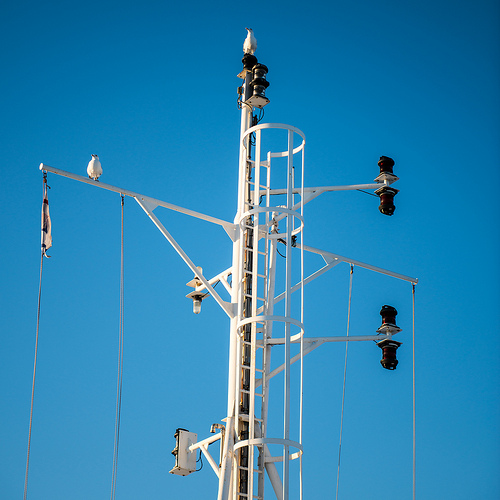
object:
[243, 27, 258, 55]
bird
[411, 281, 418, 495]
lines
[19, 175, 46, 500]
lines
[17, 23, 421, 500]
tower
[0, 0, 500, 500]
clouds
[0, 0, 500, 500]
blue sky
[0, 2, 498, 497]
no clouds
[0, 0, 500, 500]
blue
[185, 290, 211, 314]
bulb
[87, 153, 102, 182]
bird